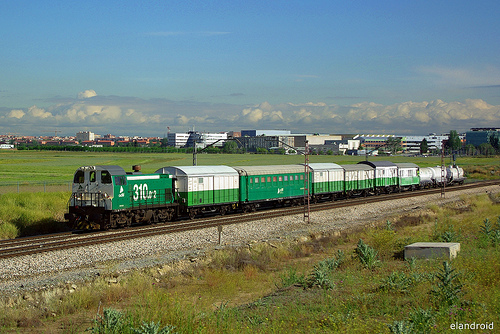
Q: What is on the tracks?
A: Train.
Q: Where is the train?
A: A field.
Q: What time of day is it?
A: Daytime.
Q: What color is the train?
A: Green and white.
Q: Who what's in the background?
A: Buildings.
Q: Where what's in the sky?
A: Clouds.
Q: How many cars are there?
A: 8.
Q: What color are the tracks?
A: Brown.